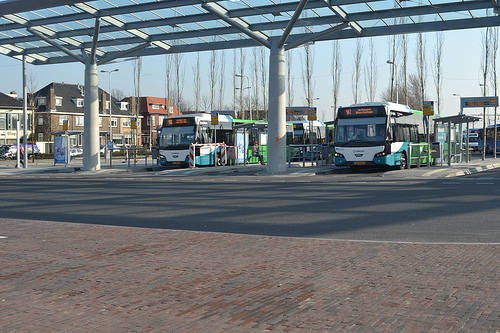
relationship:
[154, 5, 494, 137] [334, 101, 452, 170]
trees behind bus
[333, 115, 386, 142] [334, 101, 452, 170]
window of bus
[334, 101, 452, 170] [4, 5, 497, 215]
bus at bus stop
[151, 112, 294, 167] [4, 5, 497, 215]
bus at bus stop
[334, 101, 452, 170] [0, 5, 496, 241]
bus at a bus stop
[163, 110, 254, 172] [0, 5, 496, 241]
bus at a bus stop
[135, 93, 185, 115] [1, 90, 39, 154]
red roof on top of house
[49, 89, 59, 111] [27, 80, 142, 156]
chimney on building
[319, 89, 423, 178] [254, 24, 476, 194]
bus sitting at bus station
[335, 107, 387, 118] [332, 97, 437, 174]
display of bus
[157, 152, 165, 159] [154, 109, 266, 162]
headlight on bus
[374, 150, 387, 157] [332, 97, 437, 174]
headlight on bus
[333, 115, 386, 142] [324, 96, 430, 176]
window on bus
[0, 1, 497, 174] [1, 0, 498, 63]
terminal has roof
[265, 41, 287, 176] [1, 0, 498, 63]
pylon supporting roof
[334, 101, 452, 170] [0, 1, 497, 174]
bus parked at terminal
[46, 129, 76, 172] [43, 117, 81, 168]
placard on shelter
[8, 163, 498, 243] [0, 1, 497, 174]
ground across from terminal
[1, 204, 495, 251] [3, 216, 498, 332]
line beside road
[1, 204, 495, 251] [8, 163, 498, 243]
line beside ground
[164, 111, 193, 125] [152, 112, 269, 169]
display on bus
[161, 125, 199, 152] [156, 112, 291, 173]
front window on bus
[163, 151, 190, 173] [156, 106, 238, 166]
plate on bus